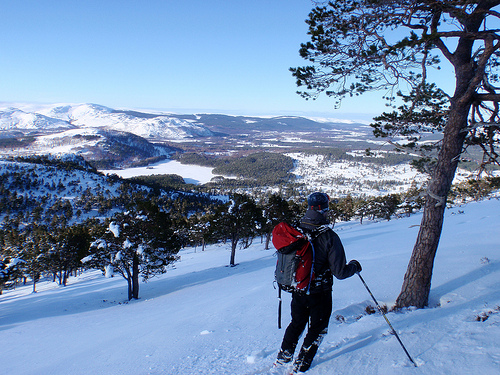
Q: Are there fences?
A: No, there are no fences.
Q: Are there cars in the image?
A: No, there are no cars.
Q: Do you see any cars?
A: No, there are no cars.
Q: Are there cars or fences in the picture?
A: No, there are no cars or fences.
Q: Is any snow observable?
A: Yes, there is snow.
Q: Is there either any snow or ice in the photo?
A: Yes, there is snow.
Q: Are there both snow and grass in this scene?
A: No, there is snow but no grass.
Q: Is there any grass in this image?
A: No, there is no grass.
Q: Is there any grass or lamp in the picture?
A: No, there are no grass or lamps.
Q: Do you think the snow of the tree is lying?
A: Yes, the snow is lying.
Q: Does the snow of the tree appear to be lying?
A: Yes, the snow is lying.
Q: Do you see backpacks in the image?
A: Yes, there is a backpack.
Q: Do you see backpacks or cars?
A: Yes, there is a backpack.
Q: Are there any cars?
A: No, there are no cars.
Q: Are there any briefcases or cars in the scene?
A: No, there are no cars or briefcases.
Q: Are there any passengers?
A: No, there are no passengers.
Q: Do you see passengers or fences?
A: No, there are no passengers or fences.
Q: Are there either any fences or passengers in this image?
A: No, there are no passengers or fences.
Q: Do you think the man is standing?
A: Yes, the man is standing.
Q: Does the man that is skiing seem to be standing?
A: Yes, the man is standing.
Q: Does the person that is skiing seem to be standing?
A: Yes, the man is standing.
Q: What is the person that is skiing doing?
A: The man is standing.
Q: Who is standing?
A: The man is standing.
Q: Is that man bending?
A: No, the man is standing.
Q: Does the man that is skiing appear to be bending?
A: No, the man is standing.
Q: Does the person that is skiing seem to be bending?
A: No, the man is standing.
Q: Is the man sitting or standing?
A: The man is standing.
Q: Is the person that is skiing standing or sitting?
A: The man is standing.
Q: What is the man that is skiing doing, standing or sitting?
A: The man is standing.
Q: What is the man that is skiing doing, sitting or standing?
A: The man is standing.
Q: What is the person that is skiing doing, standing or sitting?
A: The man is standing.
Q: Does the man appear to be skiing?
A: Yes, the man is skiing.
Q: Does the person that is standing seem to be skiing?
A: Yes, the man is skiing.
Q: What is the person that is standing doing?
A: The man is skiing.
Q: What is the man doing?
A: The man is skiing.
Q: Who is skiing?
A: The man is skiing.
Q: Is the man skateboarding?
A: No, the man is skiing.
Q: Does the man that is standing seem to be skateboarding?
A: No, the man is skiing.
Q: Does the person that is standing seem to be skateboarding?
A: No, the man is skiing.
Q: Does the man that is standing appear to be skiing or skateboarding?
A: The man is skiing.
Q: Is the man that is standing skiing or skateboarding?
A: The man is skiing.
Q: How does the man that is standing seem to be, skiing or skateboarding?
A: The man is skiing.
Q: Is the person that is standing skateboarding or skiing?
A: The man is skiing.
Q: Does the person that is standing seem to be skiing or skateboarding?
A: The man is skiing.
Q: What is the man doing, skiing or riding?
A: The man is skiing.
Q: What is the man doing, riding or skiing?
A: The man is skiing.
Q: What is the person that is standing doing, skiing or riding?
A: The man is skiing.